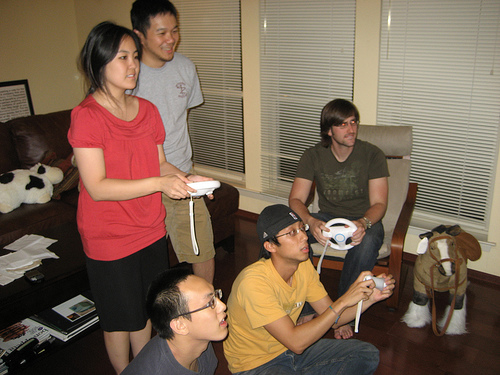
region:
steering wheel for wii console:
[323, 215, 358, 253]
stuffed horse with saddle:
[410, 222, 479, 339]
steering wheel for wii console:
[185, 177, 224, 200]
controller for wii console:
[362, 275, 394, 327]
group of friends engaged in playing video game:
[77, 0, 387, 373]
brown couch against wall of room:
[0, 113, 227, 236]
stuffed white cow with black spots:
[0, 157, 64, 217]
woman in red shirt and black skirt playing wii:
[73, 18, 168, 372]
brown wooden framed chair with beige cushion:
[292, 125, 419, 298]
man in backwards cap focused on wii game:
[230, 204, 391, 372]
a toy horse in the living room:
[393, 220, 483, 347]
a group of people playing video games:
[68, 13, 408, 373]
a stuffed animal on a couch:
[0, 156, 63, 216]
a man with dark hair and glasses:
[125, 256, 230, 371]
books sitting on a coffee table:
[0, 279, 88, 373]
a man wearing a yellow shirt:
[245, 204, 313, 372]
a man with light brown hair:
[296, 94, 392, 244]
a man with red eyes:
[327, 113, 364, 135]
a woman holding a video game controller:
[73, 11, 209, 267]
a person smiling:
[123, 0, 200, 105]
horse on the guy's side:
[405, 223, 479, 338]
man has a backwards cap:
[254, 201, 301, 260]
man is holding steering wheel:
[320, 218, 358, 259]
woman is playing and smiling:
[77, 23, 213, 311]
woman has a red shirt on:
[52, 21, 182, 335]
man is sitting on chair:
[295, 95, 410, 281]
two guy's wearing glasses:
[156, 206, 368, 368]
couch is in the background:
[2, 109, 239, 283]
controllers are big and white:
[175, 178, 221, 203]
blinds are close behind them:
[191, 12, 498, 121]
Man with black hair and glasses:
[143, 274, 265, 374]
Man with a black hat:
[231, 203, 306, 256]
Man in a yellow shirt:
[221, 196, 317, 371]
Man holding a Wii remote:
[227, 192, 410, 355]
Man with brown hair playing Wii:
[288, 99, 414, 244]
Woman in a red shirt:
[83, 47, 238, 334]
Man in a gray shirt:
[113, 6, 216, 204]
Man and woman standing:
[52, 3, 272, 303]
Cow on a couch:
[3, 161, 63, 241]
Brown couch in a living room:
[11, 111, 266, 272]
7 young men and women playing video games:
[16, 13, 486, 360]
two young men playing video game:
[248, 99, 438, 357]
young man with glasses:
[136, 256, 236, 352]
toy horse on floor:
[401, 216, 493, 368]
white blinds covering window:
[375, 18, 496, 98]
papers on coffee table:
[7, 203, 72, 300]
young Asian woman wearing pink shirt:
[56, 21, 142, 301]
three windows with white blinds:
[124, 5, 491, 252]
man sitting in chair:
[293, 93, 436, 214]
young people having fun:
[62, 16, 455, 341]